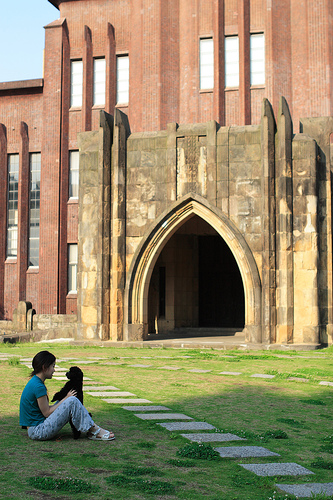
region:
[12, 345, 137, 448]
girl sitting on the grass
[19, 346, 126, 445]
girl holding a black dog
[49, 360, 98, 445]
fuzzy black dog on the grass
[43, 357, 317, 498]
stone tiles in the grass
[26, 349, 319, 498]
walking path running through the grass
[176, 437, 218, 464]
very small green plant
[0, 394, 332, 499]
shadow on the grass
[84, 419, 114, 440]
white sandals on the feet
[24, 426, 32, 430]
bit of skin is exposed underneath the shirt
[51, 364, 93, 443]
dog is on its hind legs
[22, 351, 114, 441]
A girl is sitting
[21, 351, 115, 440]
The girl is holding a dog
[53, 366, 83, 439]
The dog is black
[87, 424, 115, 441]
She is wearing sandals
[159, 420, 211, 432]
A stone foot step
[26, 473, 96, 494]
Some overgrown weeds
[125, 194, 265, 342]
A large arch way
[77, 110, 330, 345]
A stone structure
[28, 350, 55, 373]
Her hair is dark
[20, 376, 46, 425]
The shirt is blue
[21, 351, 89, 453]
this is a lady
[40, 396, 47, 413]
the lady is light skinned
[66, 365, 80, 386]
this is a dog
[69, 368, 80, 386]
the dog is black in color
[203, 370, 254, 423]
this is a grass area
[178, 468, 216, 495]
the grass is green in color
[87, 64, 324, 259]
this is a building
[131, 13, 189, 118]
this is the wall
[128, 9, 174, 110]
the wall is brown in color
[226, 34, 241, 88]
this is the window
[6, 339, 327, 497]
a green grassy yard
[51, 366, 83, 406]
a small black dog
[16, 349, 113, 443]
a woman sitting in grass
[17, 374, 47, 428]
a blue t-shirt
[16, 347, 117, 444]
a woman holding a dog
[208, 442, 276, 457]
a square grey paver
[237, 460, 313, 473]
a square grey paver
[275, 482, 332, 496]
a square grey paver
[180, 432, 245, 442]
a square grey paver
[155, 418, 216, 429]
a square grey paver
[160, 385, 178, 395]
this is the grass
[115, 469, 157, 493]
the grass is green in color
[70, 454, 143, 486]
the grass is short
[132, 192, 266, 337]
this is a door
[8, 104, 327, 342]
the building is tall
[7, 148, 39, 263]
these are some windows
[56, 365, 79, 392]
this is a dog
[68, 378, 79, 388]
the dog is black in color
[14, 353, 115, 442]
this is a woman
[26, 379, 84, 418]
the woman is holding the dog